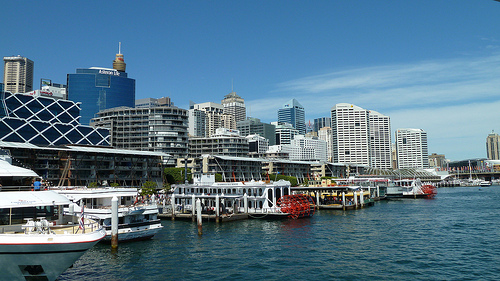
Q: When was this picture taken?
A: During the day.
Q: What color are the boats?
A: White.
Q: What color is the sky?
A: Blue.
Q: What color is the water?
A: Blue.